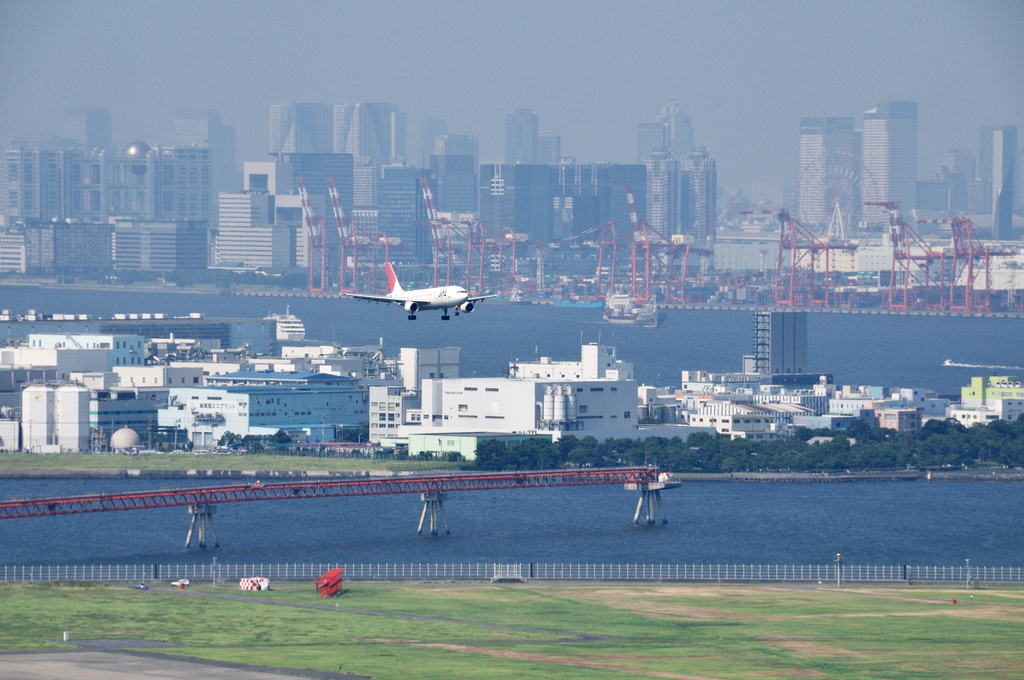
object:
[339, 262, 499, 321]
plane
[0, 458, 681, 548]
bridge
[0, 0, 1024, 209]
cloud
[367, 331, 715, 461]
building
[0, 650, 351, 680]
road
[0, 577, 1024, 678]
lawn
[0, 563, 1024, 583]
fence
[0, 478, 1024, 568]
water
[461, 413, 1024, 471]
leaves